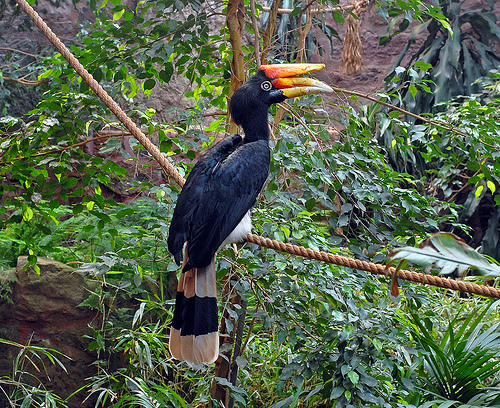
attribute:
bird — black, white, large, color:
[169, 63, 329, 358]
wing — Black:
[192, 137, 269, 269]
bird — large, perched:
[183, 70, 274, 330]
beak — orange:
[259, 60, 336, 96]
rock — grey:
[15, 227, 210, 394]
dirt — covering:
[2, 0, 457, 250]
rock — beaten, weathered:
[3, 250, 129, 387]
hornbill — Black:
[161, 59, 336, 364]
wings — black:
[165, 131, 272, 273]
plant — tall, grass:
[395, 296, 499, 398]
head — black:
[229, 84, 255, 129]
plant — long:
[426, 109, 482, 189]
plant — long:
[412, 306, 489, 400]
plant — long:
[4, 330, 85, 382]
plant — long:
[273, 328, 390, 406]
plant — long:
[326, 167, 401, 248]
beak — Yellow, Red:
[253, 50, 335, 122]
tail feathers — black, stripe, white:
[161, 242, 223, 373]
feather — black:
[221, 172, 230, 184]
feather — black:
[221, 186, 230, 199]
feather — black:
[207, 197, 215, 212]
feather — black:
[214, 212, 222, 227]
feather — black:
[216, 229, 224, 236]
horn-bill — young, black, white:
[166, 56, 331, 364]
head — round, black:
[220, 50, 338, 135]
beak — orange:
[258, 52, 340, 101]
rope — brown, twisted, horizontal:
[17, 3, 499, 305]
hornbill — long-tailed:
[154, 40, 403, 346]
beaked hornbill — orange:
[149, 45, 343, 361]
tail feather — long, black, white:
[166, 262, 184, 359]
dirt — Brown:
[307, 10, 412, 121]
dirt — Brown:
[17, 2, 94, 64]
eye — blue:
[255, 77, 270, 95]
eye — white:
[260, 80, 271, 91]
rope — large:
[15, 3, 186, 190]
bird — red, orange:
[175, 39, 327, 266]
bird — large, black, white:
[158, 61, 323, 358]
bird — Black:
[101, 35, 336, 373]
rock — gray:
[1, 242, 115, 400]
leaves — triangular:
[18, 82, 116, 281]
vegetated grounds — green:
[0, 0, 499, 406]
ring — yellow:
[258, 77, 275, 93]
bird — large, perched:
[165, 33, 366, 294]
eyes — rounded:
[260, 79, 273, 92]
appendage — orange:
[255, 57, 327, 77]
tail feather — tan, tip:
[141, 257, 244, 398]